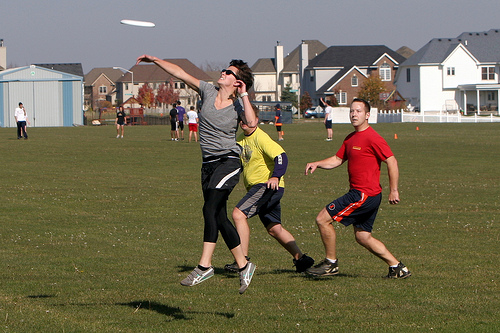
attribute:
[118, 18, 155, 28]
fridbie —  white 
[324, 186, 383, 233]
shorts — black,  black 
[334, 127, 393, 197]
shirt — red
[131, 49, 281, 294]
woman —  jumping hight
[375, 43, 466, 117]
house — white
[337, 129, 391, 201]
shirt — short sleeve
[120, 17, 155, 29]
frisbee — white, thrown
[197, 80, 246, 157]
shirt — grey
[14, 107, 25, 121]
shirt — white 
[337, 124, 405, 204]
shirt — red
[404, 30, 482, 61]
roof — black 